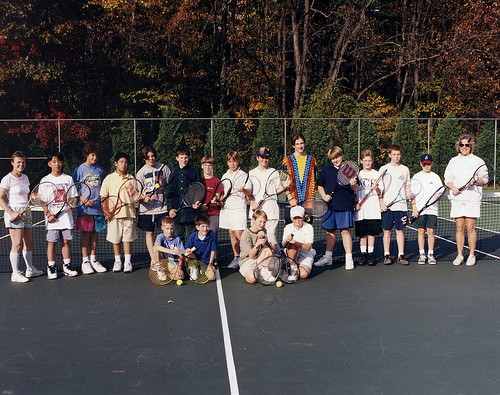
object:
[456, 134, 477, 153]
hair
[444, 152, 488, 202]
shirt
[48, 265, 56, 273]
laces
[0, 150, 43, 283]
kid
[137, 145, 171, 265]
kid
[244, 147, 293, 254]
boy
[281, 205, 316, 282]
boy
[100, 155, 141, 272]
boy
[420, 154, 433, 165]
hat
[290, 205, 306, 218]
hat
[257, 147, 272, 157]
hat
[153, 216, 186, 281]
boy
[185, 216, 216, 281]
boy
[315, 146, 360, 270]
boy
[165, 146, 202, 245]
boy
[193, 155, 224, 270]
boy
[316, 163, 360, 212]
shirt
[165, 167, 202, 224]
shirt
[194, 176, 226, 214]
shirt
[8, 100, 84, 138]
tree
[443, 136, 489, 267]
lady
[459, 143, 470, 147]
sunglasses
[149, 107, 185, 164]
evergreen trees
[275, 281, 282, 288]
ball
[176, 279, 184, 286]
ball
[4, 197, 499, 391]
court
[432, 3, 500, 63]
branches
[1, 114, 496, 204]
fence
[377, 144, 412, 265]
person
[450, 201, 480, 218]
skirt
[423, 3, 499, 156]
trees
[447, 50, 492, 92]
leaves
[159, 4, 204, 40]
leaves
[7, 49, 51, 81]
leaves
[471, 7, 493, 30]
leaves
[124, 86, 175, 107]
leaves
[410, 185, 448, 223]
racket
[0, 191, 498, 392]
tennis court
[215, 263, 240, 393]
stripe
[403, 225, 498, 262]
stripe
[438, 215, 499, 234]
stripe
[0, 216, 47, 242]
stripe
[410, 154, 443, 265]
boy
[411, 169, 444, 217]
shirt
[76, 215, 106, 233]
shorts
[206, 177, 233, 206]
racket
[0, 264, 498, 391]
floor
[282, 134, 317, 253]
woman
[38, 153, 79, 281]
kid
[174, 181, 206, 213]
rackets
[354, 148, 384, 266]
person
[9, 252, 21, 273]
socks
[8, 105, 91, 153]
foliage